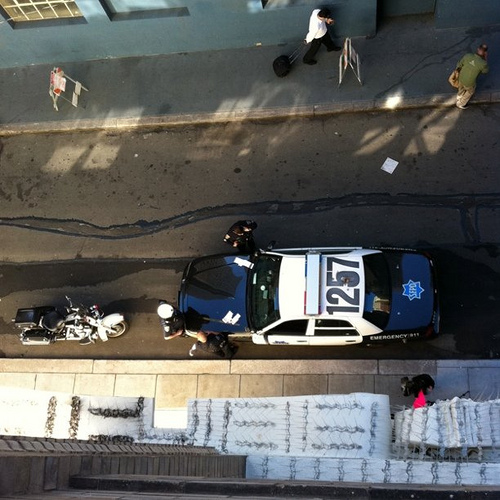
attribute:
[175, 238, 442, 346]
police car — parked, black, white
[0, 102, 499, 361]
street — black, gray, paved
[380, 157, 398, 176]
paper — white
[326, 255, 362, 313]
numbers — 1257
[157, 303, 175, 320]
helmet — white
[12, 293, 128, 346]
motorcycle — parked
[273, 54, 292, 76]
bag — black, rolled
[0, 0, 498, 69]
wall — blue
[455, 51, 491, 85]
shirt — green